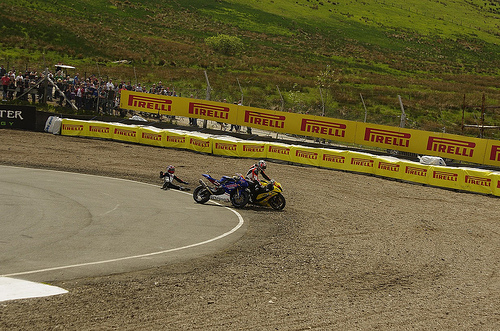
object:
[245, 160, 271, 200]
man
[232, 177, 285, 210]
motorcycle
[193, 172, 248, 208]
motorcycle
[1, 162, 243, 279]
line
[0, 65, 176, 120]
people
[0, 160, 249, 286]
racetrack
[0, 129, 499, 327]
dirt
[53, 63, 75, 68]
umbrella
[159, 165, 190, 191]
man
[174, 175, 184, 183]
arm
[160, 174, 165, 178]
arm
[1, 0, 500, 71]
hillside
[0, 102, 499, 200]
wall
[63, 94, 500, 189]
sign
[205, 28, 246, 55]
bush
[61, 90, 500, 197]
banner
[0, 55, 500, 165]
fence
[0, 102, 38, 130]
banner